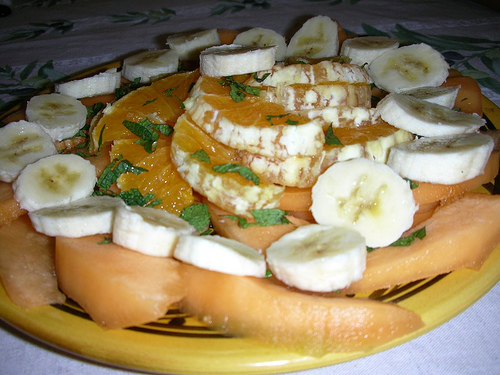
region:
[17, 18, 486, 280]
The bananas are sliced.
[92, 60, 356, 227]
The oranges are sliced.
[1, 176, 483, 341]
The catalope is sliced.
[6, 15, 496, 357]
The fruit is on the plate.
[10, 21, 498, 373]
The plate is yellow.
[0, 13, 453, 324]
The banana is around the orange.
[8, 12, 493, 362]
The melon is on the bottom.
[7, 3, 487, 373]
The table is white.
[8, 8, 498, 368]
The fuit is arranged on the plate.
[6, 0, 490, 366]
The light is shown.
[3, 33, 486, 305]
fruits that have been organized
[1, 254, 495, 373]
the edge of a yellow and brown circular plate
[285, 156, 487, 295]
bananas on top of a piece of cantaloupe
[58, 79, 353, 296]
orange slices in the middle of the fruit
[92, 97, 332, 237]
herbs sprinkled on the fruit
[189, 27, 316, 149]
one slice of banana on the oranges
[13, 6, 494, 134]
the plate is on a floral table cloth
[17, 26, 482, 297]
bananas positioned in a circle around oranges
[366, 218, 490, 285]
piece of a herb on a cantaloupe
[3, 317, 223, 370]
a slight shadow of the plate underneath it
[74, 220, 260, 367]
the plate is yellow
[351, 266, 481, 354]
the plate is yellow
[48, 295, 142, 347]
the plate is yellow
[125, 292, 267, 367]
the plate is yellow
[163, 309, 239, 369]
the plate is yellow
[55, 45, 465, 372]
the fruits are arranged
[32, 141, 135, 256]
the bananas are sliced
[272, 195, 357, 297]
the bananas are sliced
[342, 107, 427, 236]
the bananas are sliced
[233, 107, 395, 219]
the bananas are sliced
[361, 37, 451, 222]
the bananas are sliced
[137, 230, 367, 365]
the melon is orange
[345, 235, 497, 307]
the melon is orange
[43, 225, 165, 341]
the melon is orange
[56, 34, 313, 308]
Fruit on a plate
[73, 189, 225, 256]
Bananas on a plate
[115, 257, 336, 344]
Melon on a plate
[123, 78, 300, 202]
orange slices on a plate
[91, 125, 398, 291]
Bananas oranges and melon on a plate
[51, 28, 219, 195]
plate on a table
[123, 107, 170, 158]
chives on a plate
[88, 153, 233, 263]
bananas and oranges on a plate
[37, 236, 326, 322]
Melon and bananas on a plate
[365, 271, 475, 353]
Brown plate on table